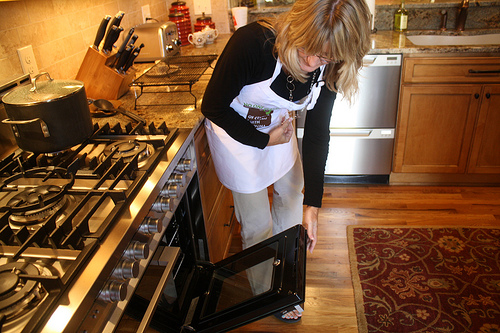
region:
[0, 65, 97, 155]
a cooking pot on a stove top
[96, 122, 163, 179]
a burner of a cook stove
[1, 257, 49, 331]
a burner of a cook stove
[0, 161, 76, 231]
a burner of a cook stove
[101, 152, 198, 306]
the control knobs of a gas stove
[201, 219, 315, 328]
a door of an oven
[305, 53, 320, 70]
the nose of a person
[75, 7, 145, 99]
a knife holder with knives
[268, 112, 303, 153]
the hand of a person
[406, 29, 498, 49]
a sink in a kitchen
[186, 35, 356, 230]
a woman wearing a apron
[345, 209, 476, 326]
a rug on the floor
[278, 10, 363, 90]
a woman with blonde hair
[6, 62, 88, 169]
a black pot with a clear lid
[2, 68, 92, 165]
a black pot with silver handles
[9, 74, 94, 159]
a black pot sitting on the stove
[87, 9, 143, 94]
a knife set with black handles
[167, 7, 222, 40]
three red canisters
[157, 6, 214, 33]
a red canister set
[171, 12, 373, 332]
a woman looking into the oven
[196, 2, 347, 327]
woman standing in the kitchen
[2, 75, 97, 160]
large pot on the stovetop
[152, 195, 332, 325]
oven door is open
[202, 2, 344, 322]
woman wearing a white apron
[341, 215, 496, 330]
rug on the floor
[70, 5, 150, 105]
wooden block filled with knives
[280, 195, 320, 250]
hand on the corner of the oven door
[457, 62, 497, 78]
handle on the drawer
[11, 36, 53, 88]
outlet on the wall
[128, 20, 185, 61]
silver toaster sitting on the counter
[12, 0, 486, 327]
A woman looking into an oven.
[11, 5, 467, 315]
A woman in a kitchen.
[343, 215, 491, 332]
Area rug on the floor.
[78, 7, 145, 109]
A set of kitchen knives.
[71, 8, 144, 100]
A wooden holder for knife set.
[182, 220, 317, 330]
Door to over is open.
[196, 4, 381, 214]
Woman with blonde hair.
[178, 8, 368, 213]
A woman wearing a white apron.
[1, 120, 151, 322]
Burners on a stove.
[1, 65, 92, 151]
Large cooking pot with lid.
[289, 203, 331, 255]
hand on a black door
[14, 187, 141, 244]
black grates on a stovetop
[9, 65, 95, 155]
grey pot on stove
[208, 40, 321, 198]
white apron on a woman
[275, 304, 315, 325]
woman's toes in a sandle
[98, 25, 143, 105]
knife block with knives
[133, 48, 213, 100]
black cooling rack on counter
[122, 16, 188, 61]
silver toaster on counter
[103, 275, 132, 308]
silver knob on oven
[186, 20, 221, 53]
white porcelain creamer cup